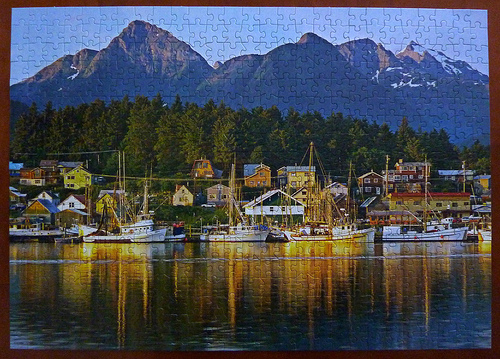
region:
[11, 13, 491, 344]
many pieces of a puzzle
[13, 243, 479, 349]
a body of water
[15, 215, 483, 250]
boats in the water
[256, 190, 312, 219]
building near the boats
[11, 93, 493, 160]
trees in forest behind homes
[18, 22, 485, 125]
mountains behind the forest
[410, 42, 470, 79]
snow covered mountain cap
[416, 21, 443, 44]
piece of the puzzle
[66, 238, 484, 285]
reflection in the water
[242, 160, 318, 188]
buildings closer to forest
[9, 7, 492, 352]
Picture is of a completed jigsaw puzzle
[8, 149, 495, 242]
Scene is of a pier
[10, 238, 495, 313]
Lights from the boats reflected in the water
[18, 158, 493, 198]
Houses in background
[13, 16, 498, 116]
Mountains in background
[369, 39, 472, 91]
Snow on top of mountain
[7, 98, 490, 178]
Trees in front of mountains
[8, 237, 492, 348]
Waters are calm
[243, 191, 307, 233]
Green boathouse with white trim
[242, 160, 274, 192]
Two story home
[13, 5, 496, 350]
jogsaw puzzle on table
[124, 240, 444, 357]
reflection of boats in water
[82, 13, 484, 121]
tall mountains in background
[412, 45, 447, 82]
snow covering mountain side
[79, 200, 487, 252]
shrimp boats in harbor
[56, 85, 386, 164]
thick trees growing on land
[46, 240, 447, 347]
body of water in foreground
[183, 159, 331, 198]
small houses on hill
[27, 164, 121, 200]
small buildings on hill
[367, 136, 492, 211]
small buildings on right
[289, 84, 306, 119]
part of a bush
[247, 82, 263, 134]
part of a hill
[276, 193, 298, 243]
part of a building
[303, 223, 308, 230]
part of a boat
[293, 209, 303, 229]
edge of a boat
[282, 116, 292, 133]
part of a forest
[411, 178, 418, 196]
part of a house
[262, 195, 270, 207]
part of a house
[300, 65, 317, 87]
part of a mountain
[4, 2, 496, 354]
a completed jigsaw puzzle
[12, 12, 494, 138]
mountain ranges and a forest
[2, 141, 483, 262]
a city with a pier and harbor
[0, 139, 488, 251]
many boats on the pier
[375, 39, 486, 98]
a partially snowy mountain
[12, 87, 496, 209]
a deep forest with tall trees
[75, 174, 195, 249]
fishing boat on shore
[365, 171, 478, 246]
fishing boat on shore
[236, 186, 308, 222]
a tent like house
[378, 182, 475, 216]
a building with red roofing